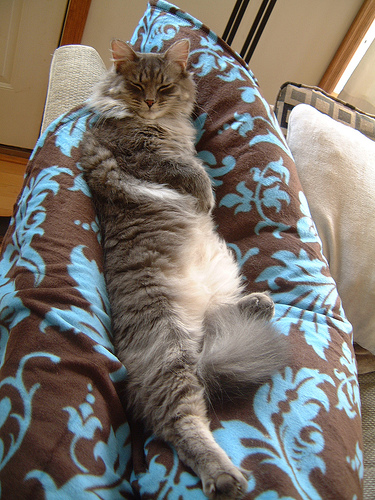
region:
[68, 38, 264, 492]
A gray cat lying on the couch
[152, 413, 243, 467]
The leg of the gray cat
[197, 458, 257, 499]
The paw of the cat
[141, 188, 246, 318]
The stomach of the cat is white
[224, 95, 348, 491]
The blanket is brown and blue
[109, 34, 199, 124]
The head of the cat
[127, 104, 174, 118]
The cat lips are smiling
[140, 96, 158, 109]
The nose of the cat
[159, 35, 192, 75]
The ear of the cat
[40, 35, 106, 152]
The color of the couch is beige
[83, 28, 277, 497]
cat lying on back on blanket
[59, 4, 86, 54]
wood trim around door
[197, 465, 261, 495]
paw of cat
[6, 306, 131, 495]
brown and blue patch of blanket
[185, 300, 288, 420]
tail of cat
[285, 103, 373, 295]
beige cushion to sofa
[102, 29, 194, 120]
head of a cat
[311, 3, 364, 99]
wood window frame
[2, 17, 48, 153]
exterior door of home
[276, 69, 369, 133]
pattern on sofa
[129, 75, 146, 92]
the cat's right eye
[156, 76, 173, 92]
the cat's left eye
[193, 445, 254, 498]
the cat's right back paw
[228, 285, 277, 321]
the cat's back left paw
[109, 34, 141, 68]
the cat's right ear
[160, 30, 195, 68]
the cat's left ear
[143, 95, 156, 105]
the nose on the cat's face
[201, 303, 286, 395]
the end of the cat's tail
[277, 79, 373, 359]
the pillow next to the cat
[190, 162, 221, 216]
the cat's front right paw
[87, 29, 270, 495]
A cat laying on its back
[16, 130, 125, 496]
A blue and brown blanket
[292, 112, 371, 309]
A white pillw on a couch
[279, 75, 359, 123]
a pillow that has squares on it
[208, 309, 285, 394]
A tail between a cats legs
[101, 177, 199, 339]
fur on a cat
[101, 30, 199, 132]
The head of a cat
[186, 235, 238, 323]
White fur on a cat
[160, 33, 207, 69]
A cat's ear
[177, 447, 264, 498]
The paw of a cat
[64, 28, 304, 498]
a gray and white cat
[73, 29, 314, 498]
a cat lying out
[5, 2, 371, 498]
a black and blue blanket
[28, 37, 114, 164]
a gray sofa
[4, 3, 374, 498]
scene is inside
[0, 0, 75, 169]
a white door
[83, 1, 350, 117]
a white wall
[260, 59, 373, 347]
a couple of pillows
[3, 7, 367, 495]
inside of a house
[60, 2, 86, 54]
a brown door frame